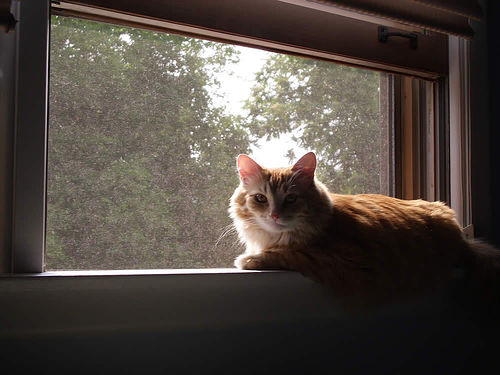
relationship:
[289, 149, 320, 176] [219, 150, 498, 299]
ear of cat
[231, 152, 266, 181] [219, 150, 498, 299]
ear of cat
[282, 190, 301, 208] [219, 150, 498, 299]
eye of cat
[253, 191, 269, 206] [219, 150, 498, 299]
eye of cat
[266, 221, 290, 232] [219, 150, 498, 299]
mouth of cat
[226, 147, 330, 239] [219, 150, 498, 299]
head of cat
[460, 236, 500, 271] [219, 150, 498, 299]
tail of cat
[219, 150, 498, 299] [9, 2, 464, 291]
cat sitting in window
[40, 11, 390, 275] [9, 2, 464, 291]
trees outside window